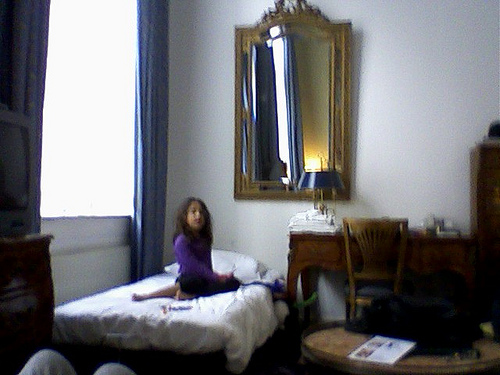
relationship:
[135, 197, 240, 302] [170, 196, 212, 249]
person has hair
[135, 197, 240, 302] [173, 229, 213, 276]
person wears purple shirt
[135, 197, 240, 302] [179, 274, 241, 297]
person wears pants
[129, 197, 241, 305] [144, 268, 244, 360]
person on bed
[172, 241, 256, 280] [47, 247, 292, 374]
pillow on bed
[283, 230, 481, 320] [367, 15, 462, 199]
desk near wall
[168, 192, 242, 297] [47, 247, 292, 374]
girl on bed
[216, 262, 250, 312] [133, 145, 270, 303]
knees on photographer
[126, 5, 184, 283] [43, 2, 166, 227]
drapes on window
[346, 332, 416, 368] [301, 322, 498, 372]
material on table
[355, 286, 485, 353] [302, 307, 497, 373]
backpack on table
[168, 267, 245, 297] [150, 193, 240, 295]
pants on girl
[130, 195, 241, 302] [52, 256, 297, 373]
girl on bed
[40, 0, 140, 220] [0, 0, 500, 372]
window in room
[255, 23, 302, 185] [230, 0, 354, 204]
reflection in mirror